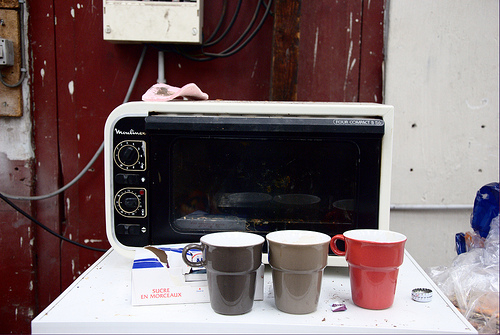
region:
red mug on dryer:
[334, 221, 399, 316]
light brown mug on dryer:
[264, 231, 351, 329]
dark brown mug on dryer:
[177, 225, 234, 315]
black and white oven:
[117, 91, 419, 276]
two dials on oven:
[101, 137, 139, 257]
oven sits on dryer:
[90, 90, 412, 290]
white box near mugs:
[134, 227, 234, 322]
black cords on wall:
[201, 13, 265, 71]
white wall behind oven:
[414, 38, 476, 226]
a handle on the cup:
[331, 230, 344, 254]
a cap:
[411, 283, 435, 302]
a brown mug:
[267, 235, 327, 319]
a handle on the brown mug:
[182, 242, 200, 267]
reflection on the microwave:
[196, 186, 341, 221]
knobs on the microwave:
[113, 143, 140, 166]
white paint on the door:
[61, 76, 78, 106]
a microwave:
[100, 98, 398, 228]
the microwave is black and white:
[100, 102, 394, 216]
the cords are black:
[215, 16, 262, 44]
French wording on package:
[134, 284, 185, 302]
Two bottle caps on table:
[408, 286, 433, 305]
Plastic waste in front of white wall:
[435, 180, 498, 330]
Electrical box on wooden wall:
[91, 0, 215, 44]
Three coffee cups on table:
[182, 230, 408, 320]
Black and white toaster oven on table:
[102, 98, 399, 265]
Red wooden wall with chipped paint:
[0, 3, 380, 320]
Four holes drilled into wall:
[406, 116, 488, 182]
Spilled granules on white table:
[321, 277, 351, 327]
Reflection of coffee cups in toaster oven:
[216, 181, 380, 220]